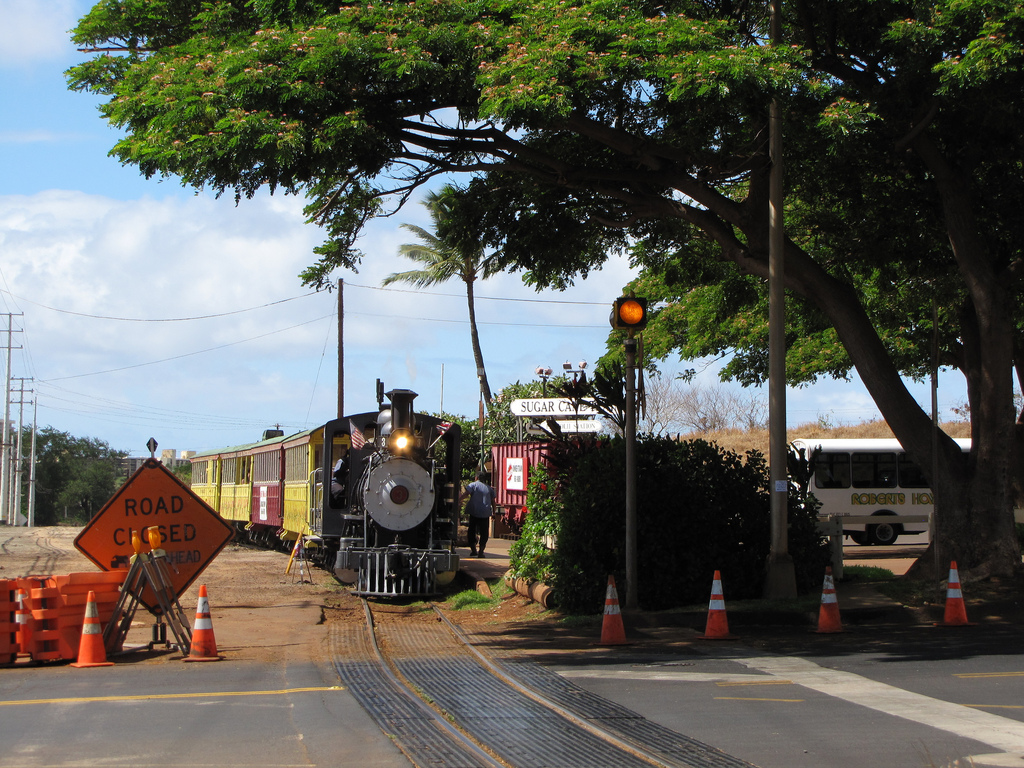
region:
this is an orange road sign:
[83, 410, 232, 660]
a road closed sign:
[52, 408, 280, 633]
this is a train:
[163, 344, 538, 645]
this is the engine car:
[301, 376, 488, 626]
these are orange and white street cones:
[7, 534, 1014, 674]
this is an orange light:
[607, 284, 650, 336]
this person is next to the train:
[453, 433, 508, 564]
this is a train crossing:
[380, 664, 713, 760]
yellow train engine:
[228, 405, 503, 618]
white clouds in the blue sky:
[35, 274, 81, 338]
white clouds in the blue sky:
[125, 282, 183, 331]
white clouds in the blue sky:
[225, 326, 309, 413]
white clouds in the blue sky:
[196, 230, 269, 297]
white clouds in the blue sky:
[32, 221, 72, 273]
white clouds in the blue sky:
[84, 323, 212, 431]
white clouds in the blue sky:
[52, 224, 113, 285]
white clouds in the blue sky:
[125, 233, 221, 335]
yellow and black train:
[206, 405, 479, 590]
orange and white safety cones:
[572, 546, 984, 644]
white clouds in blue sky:
[158, 312, 223, 373]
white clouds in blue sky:
[200, 391, 262, 434]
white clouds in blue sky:
[88, 282, 159, 349]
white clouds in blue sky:
[216, 209, 280, 279]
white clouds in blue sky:
[6, 183, 77, 270]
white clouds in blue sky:
[370, 310, 431, 350]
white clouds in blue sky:
[490, 304, 561, 366]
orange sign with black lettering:
[69, 461, 251, 626]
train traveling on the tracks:
[168, 389, 441, 598]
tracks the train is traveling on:
[357, 586, 664, 765]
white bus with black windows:
[783, 409, 993, 552]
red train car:
[246, 442, 278, 525]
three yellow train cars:
[189, 425, 325, 543]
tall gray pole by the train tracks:
[762, 90, 795, 604]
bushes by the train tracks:
[503, 422, 826, 599]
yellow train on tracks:
[211, 393, 452, 586]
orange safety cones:
[5, 568, 266, 682]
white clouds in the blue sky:
[120, 327, 179, 389]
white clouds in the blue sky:
[193, 368, 241, 398]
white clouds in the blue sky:
[271, 292, 310, 344]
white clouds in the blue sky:
[215, 252, 258, 297]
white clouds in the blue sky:
[41, 265, 111, 330]